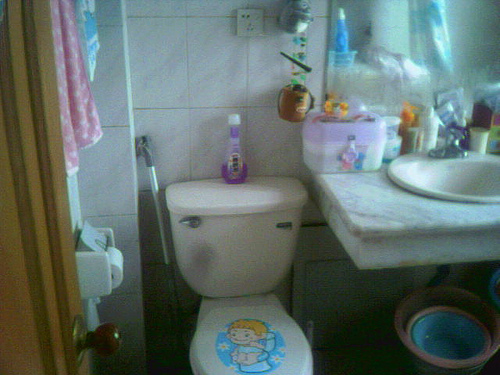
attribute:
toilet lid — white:
[188, 302, 320, 374]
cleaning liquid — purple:
[219, 110, 250, 187]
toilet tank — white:
[162, 172, 311, 299]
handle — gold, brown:
[66, 315, 125, 364]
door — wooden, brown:
[0, 1, 100, 374]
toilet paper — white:
[103, 239, 128, 297]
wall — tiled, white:
[128, 2, 499, 371]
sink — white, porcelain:
[384, 145, 499, 211]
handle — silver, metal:
[175, 217, 203, 231]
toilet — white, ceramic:
[160, 174, 320, 374]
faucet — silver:
[424, 124, 472, 161]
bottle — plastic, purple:
[219, 109, 251, 189]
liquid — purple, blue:
[223, 161, 248, 186]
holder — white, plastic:
[74, 224, 118, 305]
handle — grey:
[137, 135, 156, 170]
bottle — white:
[416, 105, 441, 157]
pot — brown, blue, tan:
[391, 282, 500, 372]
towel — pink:
[47, 1, 108, 177]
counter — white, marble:
[304, 155, 499, 269]